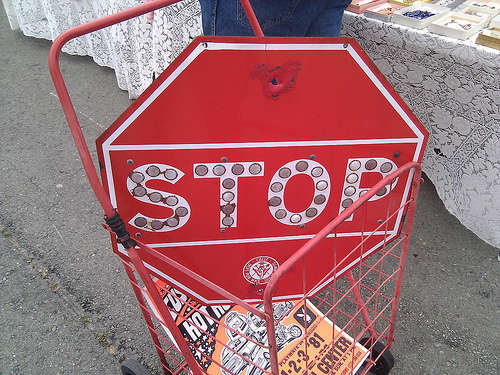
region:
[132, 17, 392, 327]
This is a sign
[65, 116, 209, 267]
This is a stop sign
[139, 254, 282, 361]
This is a poster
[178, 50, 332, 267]
The sign is red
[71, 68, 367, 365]
The sign has eight sides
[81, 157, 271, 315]
This is a cart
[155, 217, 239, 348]
The car is red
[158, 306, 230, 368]
The cart is made of metal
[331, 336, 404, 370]
This is a tire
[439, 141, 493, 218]
This is a lace tablecloth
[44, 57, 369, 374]
the basket is red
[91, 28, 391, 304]
a red STOP sign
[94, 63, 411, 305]
The sign is red.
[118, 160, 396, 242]
The lettering has spots.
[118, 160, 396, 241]
The lettering is white.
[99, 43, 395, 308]
The edge is white.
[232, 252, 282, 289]
The logo is circular.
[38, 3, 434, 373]
The cart is red.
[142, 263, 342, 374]
The sign is orange.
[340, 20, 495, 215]
The table cloth is white.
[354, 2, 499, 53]
Jewlery is on the table.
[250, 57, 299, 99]
The sign is dirty.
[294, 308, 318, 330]
Small playboy on the corner.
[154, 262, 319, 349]
Orange sign in the bottom.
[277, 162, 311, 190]
Small circles in the O.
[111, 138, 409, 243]
Word STOP on the sign.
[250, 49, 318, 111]
Whole in the top of sign.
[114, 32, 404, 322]
White line on stop sign.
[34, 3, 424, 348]
White line in an octagon.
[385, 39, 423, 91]
White table cloth on table.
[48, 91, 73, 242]
Small dirt on the ground.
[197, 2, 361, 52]
Man in blue jeans by table.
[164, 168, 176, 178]
dot on stop sign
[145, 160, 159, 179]
dot on stop sign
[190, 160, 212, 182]
dot on stop sign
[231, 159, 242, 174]
dot on stop sign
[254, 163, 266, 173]
dot on stop sign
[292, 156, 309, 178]
dot on stop sign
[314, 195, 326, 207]
dot on stop sign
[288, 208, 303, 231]
dot on stop sign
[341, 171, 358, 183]
dot on stop sign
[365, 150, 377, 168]
dot on stop sign